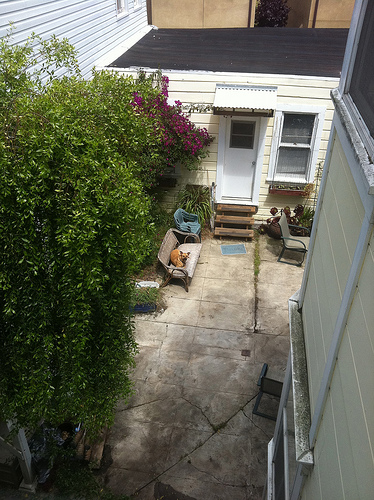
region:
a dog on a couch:
[168, 242, 198, 275]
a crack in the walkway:
[191, 393, 233, 442]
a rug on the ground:
[216, 237, 254, 264]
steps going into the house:
[216, 194, 252, 245]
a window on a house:
[284, 119, 312, 174]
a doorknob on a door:
[247, 156, 261, 172]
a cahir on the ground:
[168, 204, 212, 240]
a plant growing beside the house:
[184, 180, 212, 220]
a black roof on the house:
[153, 37, 214, 69]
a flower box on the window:
[271, 179, 305, 197]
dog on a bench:
[171, 244, 189, 265]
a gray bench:
[159, 228, 201, 289]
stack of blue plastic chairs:
[175, 208, 200, 235]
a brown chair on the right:
[279, 212, 309, 261]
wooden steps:
[216, 202, 258, 239]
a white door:
[224, 118, 258, 201]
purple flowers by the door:
[126, 78, 213, 154]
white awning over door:
[212, 85, 278, 114]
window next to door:
[278, 103, 319, 191]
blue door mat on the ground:
[221, 242, 245, 253]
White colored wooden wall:
[328, 421, 368, 488]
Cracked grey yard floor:
[172, 389, 242, 476]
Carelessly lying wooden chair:
[248, 359, 276, 419]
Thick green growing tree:
[31, 317, 104, 376]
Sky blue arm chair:
[172, 202, 195, 219]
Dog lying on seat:
[164, 246, 195, 266]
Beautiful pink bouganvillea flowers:
[170, 110, 191, 136]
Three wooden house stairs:
[215, 201, 255, 237]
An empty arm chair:
[277, 209, 305, 265]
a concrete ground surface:
[91, 228, 306, 498]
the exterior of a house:
[261, 0, 373, 499]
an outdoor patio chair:
[251, 362, 285, 420]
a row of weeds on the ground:
[252, 227, 259, 313]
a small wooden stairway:
[214, 203, 255, 240]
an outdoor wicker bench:
[157, 228, 201, 292]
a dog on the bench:
[169, 248, 189, 268]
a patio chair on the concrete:
[276, 212, 310, 266]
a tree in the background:
[253, 0, 292, 27]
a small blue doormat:
[219, 242, 246, 254]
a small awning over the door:
[209, 81, 283, 122]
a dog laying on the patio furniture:
[170, 243, 190, 266]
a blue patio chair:
[172, 207, 207, 235]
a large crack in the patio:
[201, 413, 236, 435]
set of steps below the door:
[212, 201, 259, 242]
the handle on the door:
[251, 155, 258, 174]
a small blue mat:
[218, 240, 247, 257]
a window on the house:
[273, 110, 316, 178]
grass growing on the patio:
[248, 236, 268, 325]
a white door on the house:
[226, 119, 258, 200]